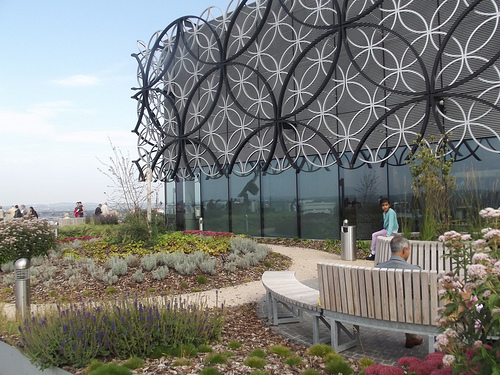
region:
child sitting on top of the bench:
[370, 198, 397, 255]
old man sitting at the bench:
[372, 235, 419, 268]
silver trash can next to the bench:
[338, 224, 353, 260]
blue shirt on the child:
[380, 209, 399, 231]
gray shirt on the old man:
[372, 254, 422, 271]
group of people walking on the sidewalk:
[0, 205, 110, 220]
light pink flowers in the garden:
[435, 207, 499, 369]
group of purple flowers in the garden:
[18, 296, 224, 358]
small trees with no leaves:
[101, 153, 158, 236]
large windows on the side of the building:
[164, 141, 499, 238]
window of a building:
[163, 170, 196, 230]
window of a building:
[203, 172, 240, 242]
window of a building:
[230, 165, 256, 222]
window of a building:
[265, 173, 290, 218]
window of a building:
[306, 173, 330, 219]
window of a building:
[358, 167, 380, 215]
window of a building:
[377, 151, 424, 198]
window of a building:
[457, 144, 490, 194]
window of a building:
[450, 194, 487, 239]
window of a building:
[342, 207, 371, 247]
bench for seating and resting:
[257, 262, 439, 351]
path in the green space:
[58, 283, 294, 305]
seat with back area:
[312, 263, 459, 327]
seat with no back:
[263, 265, 319, 323]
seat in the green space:
[383, 227, 455, 269]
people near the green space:
[5, 187, 120, 218]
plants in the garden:
[53, 248, 240, 290]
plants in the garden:
[23, 290, 231, 348]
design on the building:
[136, 28, 493, 161]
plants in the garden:
[78, 226, 220, 253]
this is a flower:
[168, 251, 196, 275]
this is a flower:
[452, 255, 490, 306]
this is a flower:
[428, 219, 472, 266]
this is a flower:
[475, 215, 497, 249]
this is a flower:
[100, 235, 142, 290]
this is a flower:
[424, 345, 466, 373]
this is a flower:
[412, 315, 473, 356]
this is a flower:
[462, 249, 486, 284]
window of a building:
[168, 184, 203, 224]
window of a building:
[200, 170, 230, 212]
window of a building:
[205, 207, 230, 230]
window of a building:
[234, 171, 259, 193]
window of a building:
[240, 208, 255, 224]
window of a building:
[268, 205, 289, 227]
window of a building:
[300, 168, 327, 193]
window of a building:
[313, 207, 339, 234]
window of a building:
[360, 158, 387, 183]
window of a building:
[352, 196, 376, 218]